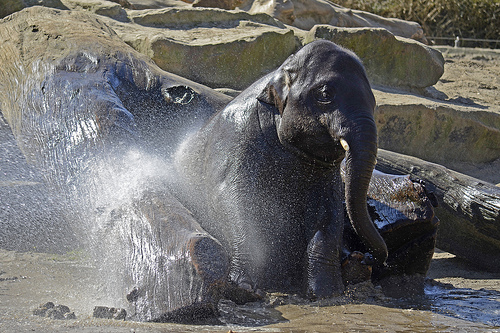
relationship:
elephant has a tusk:
[170, 40, 388, 299] [336, 132, 353, 155]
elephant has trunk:
[170, 40, 388, 299] [328, 114, 395, 259]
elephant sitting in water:
[170, 40, 388, 299] [0, 115, 499, 329]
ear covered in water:
[255, 62, 297, 116] [0, 115, 499, 329]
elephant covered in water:
[170, 40, 388, 299] [0, 115, 499, 329]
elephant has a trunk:
[170, 40, 388, 299] [328, 114, 395, 259]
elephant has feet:
[170, 40, 388, 299] [220, 237, 349, 304]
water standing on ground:
[0, 115, 499, 329] [1, 199, 497, 331]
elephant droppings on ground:
[25, 299, 79, 324] [1, 199, 497, 331]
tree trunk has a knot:
[2, 7, 495, 333] [159, 82, 201, 112]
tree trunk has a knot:
[2, 7, 495, 333] [188, 234, 233, 285]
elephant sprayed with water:
[170, 40, 388, 299] [0, 115, 499, 329]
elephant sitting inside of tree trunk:
[170, 40, 388, 299] [2, 7, 495, 333]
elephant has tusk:
[170, 40, 388, 299] [336, 132, 353, 155]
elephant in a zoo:
[170, 40, 388, 299] [1, 1, 499, 330]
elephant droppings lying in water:
[25, 299, 79, 324] [0, 115, 499, 329]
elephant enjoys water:
[170, 40, 388, 299] [0, 115, 499, 329]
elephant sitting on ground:
[170, 40, 388, 299] [1, 199, 497, 331]